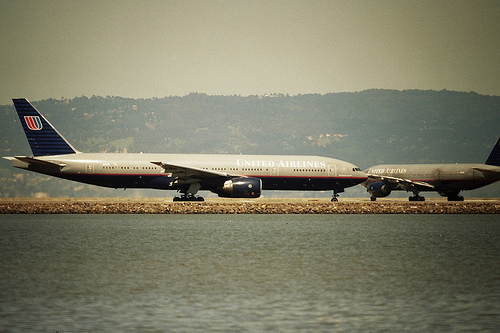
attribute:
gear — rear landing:
[167, 185, 202, 206]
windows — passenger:
[292, 168, 332, 171]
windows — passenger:
[243, 166, 269, 171]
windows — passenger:
[225, 166, 237, 171]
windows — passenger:
[140, 165, 157, 170]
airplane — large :
[360, 136, 497, 200]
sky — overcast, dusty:
[236, 10, 406, 86]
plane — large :
[1, 89, 373, 214]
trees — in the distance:
[0, 92, 495, 197]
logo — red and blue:
[24, 115, 44, 130]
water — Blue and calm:
[3, 211, 498, 330]